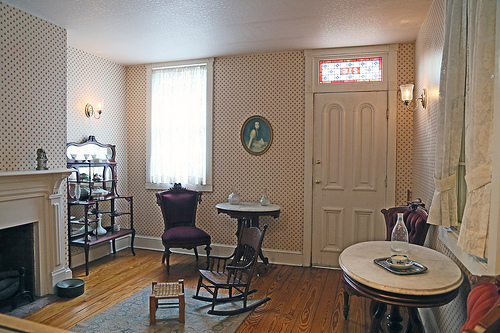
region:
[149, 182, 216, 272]
antique purple upholstered chair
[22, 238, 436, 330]
beautiful grainy wood floor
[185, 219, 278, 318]
small dark brown wooden rocking chair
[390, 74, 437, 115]
lamp mounted on the wall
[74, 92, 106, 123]
lamp mounted on the wall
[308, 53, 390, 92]
red and blue stained glass window above the door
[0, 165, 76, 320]
fire place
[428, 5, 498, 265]
white curtains pulled back from the window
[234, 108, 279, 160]
oval shaped painting of a woman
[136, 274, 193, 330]
small striped foot stool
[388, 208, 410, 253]
glass milk jug on table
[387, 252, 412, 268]
coffee cup and plate on platter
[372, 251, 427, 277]
silver platter on table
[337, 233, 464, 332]
marble-topped side table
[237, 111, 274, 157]
oval painting of young girl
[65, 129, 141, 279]
antique wood butler's table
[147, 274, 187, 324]
wood and woven straw foot rest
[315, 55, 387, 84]
stained glass window above door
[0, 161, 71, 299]
wooden fire place mantle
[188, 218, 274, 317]
a wooden rocking chair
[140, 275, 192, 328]
a wooden footstool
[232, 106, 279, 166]
a picture on the wall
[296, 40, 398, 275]
a white door in a wall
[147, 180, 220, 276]
a purple chair on the ground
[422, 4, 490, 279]
curtains around a window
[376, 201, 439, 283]
a lamp on a table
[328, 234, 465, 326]
a wooden table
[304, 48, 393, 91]
a stained glass window above a door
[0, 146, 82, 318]
a white fireplace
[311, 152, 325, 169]
lock on front door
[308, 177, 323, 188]
handle on front door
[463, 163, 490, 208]
curtain tie on right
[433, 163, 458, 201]
curtain tie on left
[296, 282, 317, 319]
smooth brown hardwood floor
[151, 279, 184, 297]
short brown stepping stand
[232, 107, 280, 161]
picture on wall in room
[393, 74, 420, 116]
light fixture on wall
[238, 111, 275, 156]
creepy picture on the wall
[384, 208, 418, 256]
clear glass bottle on the table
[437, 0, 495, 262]
white curtains on the window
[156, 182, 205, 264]
majestic purple sitting chair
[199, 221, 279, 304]
dark brown wood rocking chair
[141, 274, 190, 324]
small brown wooden ottoman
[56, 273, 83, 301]
black object next to fireplace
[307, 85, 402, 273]
white door next to table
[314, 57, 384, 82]
red and blue glass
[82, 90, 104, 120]
lamp mounted on the wall